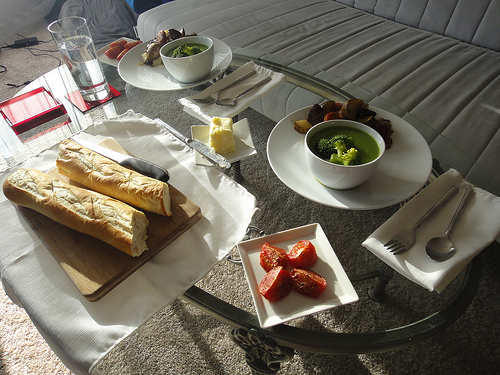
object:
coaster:
[60, 85, 128, 110]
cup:
[38, 16, 137, 106]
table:
[146, 57, 401, 295]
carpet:
[100, 305, 238, 373]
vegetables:
[292, 95, 394, 149]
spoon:
[418, 184, 480, 263]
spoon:
[214, 77, 271, 107]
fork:
[382, 180, 462, 256]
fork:
[192, 69, 271, 108]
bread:
[3, 145, 171, 260]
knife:
[67, 131, 169, 182]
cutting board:
[2, 139, 203, 303]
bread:
[56, 143, 175, 215]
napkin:
[361, 167, 498, 294]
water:
[65, 45, 115, 87]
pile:
[293, 98, 397, 149]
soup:
[307, 123, 378, 165]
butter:
[208, 117, 237, 153]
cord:
[5, 36, 42, 53]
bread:
[22, 134, 192, 278]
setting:
[374, 214, 479, 272]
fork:
[382, 220, 420, 259]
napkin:
[391, 200, 422, 225]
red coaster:
[0, 86, 66, 135]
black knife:
[70, 133, 171, 183]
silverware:
[193, 70, 256, 104]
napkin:
[176, 59, 285, 125]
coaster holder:
[0, 86, 67, 134]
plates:
[115, 25, 437, 213]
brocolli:
[317, 127, 374, 163]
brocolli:
[170, 41, 204, 55]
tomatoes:
[258, 241, 328, 302]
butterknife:
[152, 116, 231, 168]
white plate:
[268, 143, 306, 183]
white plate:
[121, 54, 154, 91]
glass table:
[235, 74, 333, 126]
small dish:
[190, 116, 256, 168]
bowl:
[304, 115, 390, 185]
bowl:
[152, 29, 216, 77]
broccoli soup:
[310, 125, 380, 166]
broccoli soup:
[163, 42, 209, 57]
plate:
[178, 120, 258, 164]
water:
[57, 31, 108, 101]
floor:
[1, 0, 496, 371]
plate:
[268, 98, 434, 212]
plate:
[239, 222, 359, 328]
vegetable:
[305, 104, 326, 125]